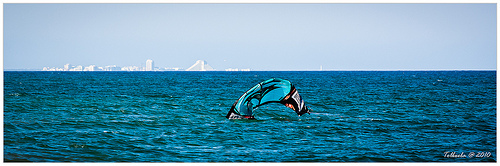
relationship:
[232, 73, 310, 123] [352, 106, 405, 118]
parasail on water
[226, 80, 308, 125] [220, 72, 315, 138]
sail for sport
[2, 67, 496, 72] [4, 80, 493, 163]
horizon on water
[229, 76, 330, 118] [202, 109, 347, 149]
parachute for landing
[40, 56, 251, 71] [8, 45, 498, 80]
city in distance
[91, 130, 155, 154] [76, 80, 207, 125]
wave in ocean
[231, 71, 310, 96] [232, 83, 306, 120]
top of sail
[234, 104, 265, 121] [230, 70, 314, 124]
base of sail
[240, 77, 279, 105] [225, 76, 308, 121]
pattern on sail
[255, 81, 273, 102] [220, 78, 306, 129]
markings on kite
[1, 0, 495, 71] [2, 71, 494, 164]
sky over ocean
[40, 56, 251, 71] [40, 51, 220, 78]
city standing in distance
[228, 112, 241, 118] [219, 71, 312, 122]
corner belonging to kite